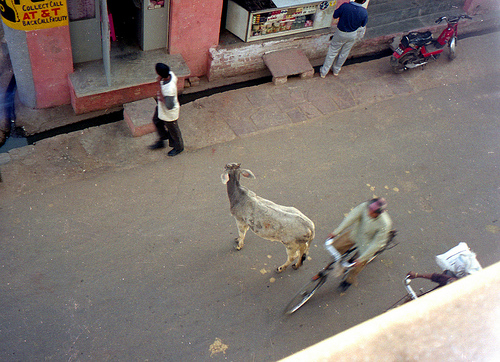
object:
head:
[219, 159, 258, 189]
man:
[148, 61, 190, 158]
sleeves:
[333, 208, 358, 238]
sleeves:
[360, 233, 391, 262]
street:
[48, 184, 209, 319]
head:
[362, 194, 392, 219]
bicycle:
[283, 228, 402, 316]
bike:
[386, 12, 471, 75]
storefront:
[2, 0, 228, 122]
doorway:
[103, 1, 171, 56]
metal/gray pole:
[99, 0, 117, 91]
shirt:
[331, 2, 370, 35]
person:
[315, 0, 370, 80]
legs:
[165, 119, 184, 157]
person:
[319, 194, 392, 297]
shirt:
[326, 196, 393, 265]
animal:
[216, 157, 316, 274]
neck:
[225, 178, 243, 191]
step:
[123, 97, 168, 136]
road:
[0, 22, 500, 360]